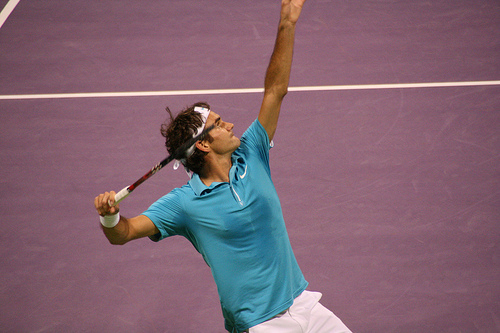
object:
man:
[93, 0, 352, 333]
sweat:
[219, 186, 283, 257]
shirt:
[137, 118, 309, 333]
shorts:
[248, 291, 361, 332]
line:
[61, 86, 206, 100]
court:
[0, 0, 500, 332]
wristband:
[97, 212, 124, 226]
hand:
[90, 190, 116, 216]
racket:
[114, 124, 212, 202]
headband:
[168, 106, 210, 172]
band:
[98, 212, 120, 228]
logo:
[238, 161, 249, 178]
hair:
[160, 102, 211, 174]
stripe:
[359, 76, 494, 101]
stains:
[222, 203, 252, 227]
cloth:
[213, 183, 284, 269]